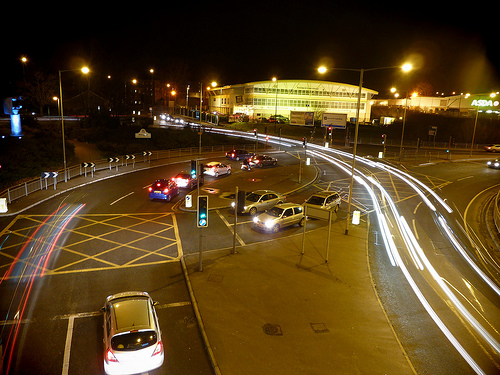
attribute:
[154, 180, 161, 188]
light — Red 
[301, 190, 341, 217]
car — blue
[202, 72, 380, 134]
building — large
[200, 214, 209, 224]
light — green 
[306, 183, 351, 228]
van — silver 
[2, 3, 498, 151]
sky — dark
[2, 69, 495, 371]
street city — busy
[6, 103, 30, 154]
blue sign — neon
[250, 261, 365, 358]
concrete — divider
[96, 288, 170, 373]
suv — white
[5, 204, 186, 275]
lines — Yellow 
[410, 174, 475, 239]
dash line — white 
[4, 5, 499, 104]
sky — black 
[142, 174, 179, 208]
car — blue 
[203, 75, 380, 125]
building — white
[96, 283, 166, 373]
car — white, stopped, back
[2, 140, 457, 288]
lines — crisscrossed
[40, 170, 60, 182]
sign — white , black 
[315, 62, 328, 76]
light — on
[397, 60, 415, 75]
light — on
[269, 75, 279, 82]
light — on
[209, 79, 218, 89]
light — on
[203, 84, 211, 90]
light — on